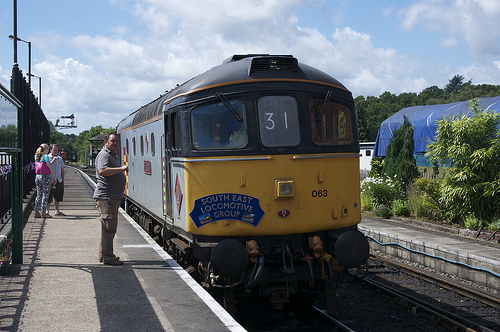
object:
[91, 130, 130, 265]
man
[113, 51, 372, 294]
train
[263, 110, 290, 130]
number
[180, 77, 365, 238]
front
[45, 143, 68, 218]
people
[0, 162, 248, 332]
sidewalk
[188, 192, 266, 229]
sign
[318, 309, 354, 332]
tracks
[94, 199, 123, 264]
pants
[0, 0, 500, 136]
sky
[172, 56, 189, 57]
clouds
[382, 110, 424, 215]
trees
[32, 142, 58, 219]
woman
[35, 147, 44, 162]
ponytail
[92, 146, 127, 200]
shirt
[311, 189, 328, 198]
number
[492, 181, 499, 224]
plants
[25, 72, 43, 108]
lights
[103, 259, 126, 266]
shoe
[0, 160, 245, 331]
platform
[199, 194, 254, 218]
south east locomotiv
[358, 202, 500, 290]
platform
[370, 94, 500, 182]
structure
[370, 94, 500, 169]
tarp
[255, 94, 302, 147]
window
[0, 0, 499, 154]
distance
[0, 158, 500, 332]
ground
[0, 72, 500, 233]
foilage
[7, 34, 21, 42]
light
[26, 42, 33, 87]
pole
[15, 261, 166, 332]
shadow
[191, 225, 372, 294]
bumper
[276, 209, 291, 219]
sensor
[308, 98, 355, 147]
window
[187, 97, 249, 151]
window